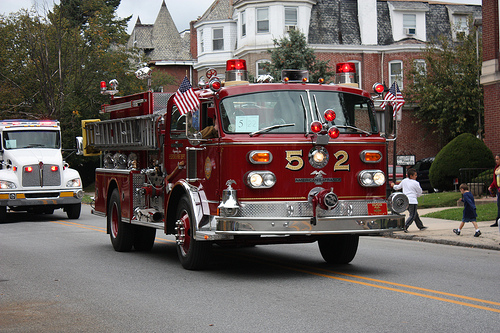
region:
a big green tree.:
[0, 0, 119, 113]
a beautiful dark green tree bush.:
[427, 132, 499, 191]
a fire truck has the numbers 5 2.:
[266, 132, 376, 192]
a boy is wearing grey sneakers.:
[450, 222, 467, 242]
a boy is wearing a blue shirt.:
[463, 197, 479, 212]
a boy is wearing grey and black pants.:
[403, 204, 427, 239]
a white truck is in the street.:
[0, 115, 95, 227]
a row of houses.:
[116, 0, 496, 78]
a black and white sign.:
[394, 151, 418, 171]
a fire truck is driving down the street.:
[23, 17, 494, 289]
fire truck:
[84, 56, 411, 272]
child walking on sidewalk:
[451, 176, 483, 241]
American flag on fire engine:
[170, 70, 196, 118]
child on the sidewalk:
[393, 165, 423, 231]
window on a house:
[385, 52, 405, 93]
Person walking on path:
[483, 145, 498, 230]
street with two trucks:
[0, 60, 495, 328]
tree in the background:
[0, 25, 175, 117]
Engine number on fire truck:
[282, 142, 357, 173]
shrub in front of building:
[423, 128, 498, 200]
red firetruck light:
[225, 58, 252, 82]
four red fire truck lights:
[206, 56, 387, 95]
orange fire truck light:
[250, 149, 274, 164]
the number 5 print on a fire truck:
[280, 146, 305, 171]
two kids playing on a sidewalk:
[393, 168, 481, 238]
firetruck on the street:
[77, 56, 409, 273]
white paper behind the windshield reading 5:
[234, 113, 258, 132]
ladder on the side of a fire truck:
[80, 114, 159, 154]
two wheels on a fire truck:
[105, 174, 219, 271]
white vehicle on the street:
[0, 116, 85, 222]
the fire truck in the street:
[57, 47, 432, 290]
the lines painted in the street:
[351, 273, 489, 329]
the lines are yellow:
[363, 275, 495, 325]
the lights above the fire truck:
[199, 53, 384, 110]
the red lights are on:
[219, 51, 381, 78]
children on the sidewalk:
[389, 153, 492, 236]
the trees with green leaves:
[10, 30, 125, 93]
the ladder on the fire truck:
[81, 115, 173, 150]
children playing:
[400, 166, 484, 237]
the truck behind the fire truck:
[1, 116, 106, 233]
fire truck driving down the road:
[75, 52, 435, 292]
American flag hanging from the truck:
[164, 80, 210, 135]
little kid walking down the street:
[447, 174, 489, 235]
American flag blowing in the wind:
[380, 84, 417, 121]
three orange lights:
[302, 109, 349, 152]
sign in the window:
[229, 112, 274, 139]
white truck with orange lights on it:
[2, 105, 87, 230]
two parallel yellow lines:
[327, 266, 494, 331]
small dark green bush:
[424, 127, 494, 204]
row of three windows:
[237, 5, 312, 40]